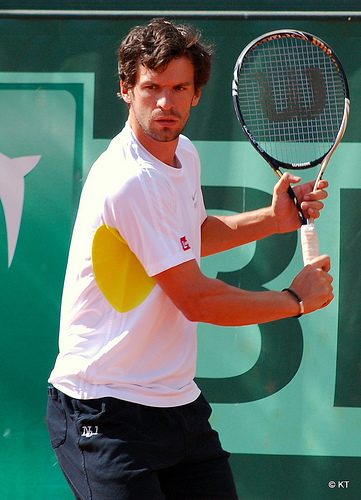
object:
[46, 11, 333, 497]
man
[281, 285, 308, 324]
bracelet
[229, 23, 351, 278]
racket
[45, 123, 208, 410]
t-shirt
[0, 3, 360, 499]
wall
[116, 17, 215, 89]
brown hair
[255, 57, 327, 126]
w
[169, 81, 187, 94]
eyes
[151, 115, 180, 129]
mouth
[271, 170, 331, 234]
hand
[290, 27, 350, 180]
orange and white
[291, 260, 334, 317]
player's hands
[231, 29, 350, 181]
hit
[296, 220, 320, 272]
handle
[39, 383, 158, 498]
bottoms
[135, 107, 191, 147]
chin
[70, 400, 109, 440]
pocket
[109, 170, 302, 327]
arm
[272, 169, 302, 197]
thumb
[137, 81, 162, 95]
eye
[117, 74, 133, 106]
ear